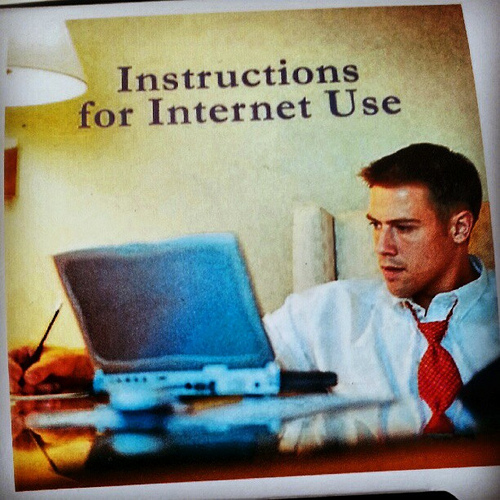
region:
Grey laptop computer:
[50, 232, 338, 409]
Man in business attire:
[10, 143, 498, 454]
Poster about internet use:
[0, 4, 498, 492]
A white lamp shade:
[1, 16, 85, 107]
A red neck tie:
[402, 300, 469, 437]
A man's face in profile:
[354, 142, 484, 309]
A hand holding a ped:
[5, 299, 92, 396]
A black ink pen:
[18, 304, 62, 396]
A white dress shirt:
[262, 256, 497, 453]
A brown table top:
[10, 377, 495, 491]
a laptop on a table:
[75, 212, 490, 487]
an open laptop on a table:
[75, 227, 369, 485]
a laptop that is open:
[79, 234, 440, 496]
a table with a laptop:
[14, 191, 411, 495]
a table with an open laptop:
[48, 215, 375, 485]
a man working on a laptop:
[274, 169, 496, 373]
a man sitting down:
[287, 171, 497, 443]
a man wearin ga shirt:
[269, 141, 490, 386]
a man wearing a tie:
[271, 179, 486, 372]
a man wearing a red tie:
[309, 202, 486, 430]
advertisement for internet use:
[26, 83, 479, 400]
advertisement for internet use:
[100, 170, 459, 481]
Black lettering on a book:
[112, 56, 131, 101]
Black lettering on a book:
[133, 69, 161, 93]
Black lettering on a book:
[161, 66, 178, 97]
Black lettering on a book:
[181, 58, 195, 95]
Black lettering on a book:
[193, 62, 214, 92]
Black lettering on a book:
[214, 66, 240, 91]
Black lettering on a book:
[239, 62, 261, 92]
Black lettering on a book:
[260, 61, 278, 90]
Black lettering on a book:
[276, 52, 292, 90]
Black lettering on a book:
[290, 58, 307, 86]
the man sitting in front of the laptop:
[7, 143, 498, 395]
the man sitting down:
[7, 143, 497, 395]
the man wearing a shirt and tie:
[7, 141, 497, 394]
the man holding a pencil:
[7, 143, 499, 397]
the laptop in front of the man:
[51, 233, 337, 395]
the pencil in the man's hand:
[14, 300, 62, 392]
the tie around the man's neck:
[408, 298, 462, 398]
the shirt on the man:
[260, 252, 499, 398]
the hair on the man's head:
[356, 143, 483, 237]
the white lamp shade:
[6, 20, 88, 107]